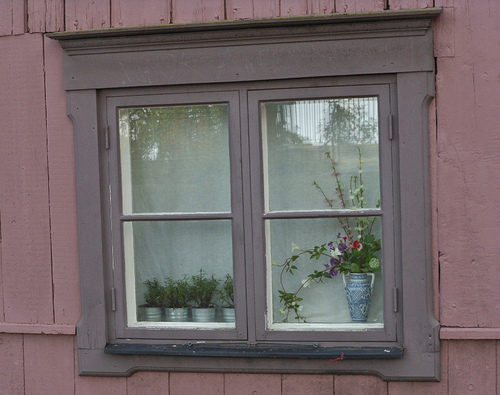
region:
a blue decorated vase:
[329, 240, 377, 325]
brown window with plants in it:
[51, 45, 436, 342]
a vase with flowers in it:
[288, 154, 410, 330]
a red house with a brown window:
[16, 42, 495, 369]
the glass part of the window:
[106, 100, 388, 329]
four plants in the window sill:
[137, 260, 274, 337]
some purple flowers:
[314, 236, 347, 288]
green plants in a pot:
[121, 254, 249, 333]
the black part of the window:
[103, 333, 410, 365]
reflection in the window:
[246, 78, 402, 165]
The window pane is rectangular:
[119, 108, 236, 328]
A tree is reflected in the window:
[138, 113, 224, 150]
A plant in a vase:
[288, 165, 383, 324]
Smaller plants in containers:
[145, 284, 235, 320]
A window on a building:
[112, 105, 378, 322]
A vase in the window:
[341, 272, 377, 319]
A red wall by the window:
[451, 128, 491, 370]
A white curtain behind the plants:
[148, 128, 220, 265]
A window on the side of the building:
[113, 99, 385, 320]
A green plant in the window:
[300, 159, 384, 271]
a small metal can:
[138, 304, 160, 322]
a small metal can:
[161, 302, 187, 320]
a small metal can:
[191, 303, 215, 324]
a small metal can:
[217, 306, 234, 323]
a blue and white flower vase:
[334, 264, 378, 323]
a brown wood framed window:
[98, 75, 406, 348]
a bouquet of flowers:
[278, 145, 383, 323]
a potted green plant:
[134, 276, 163, 324]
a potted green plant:
[161, 273, 188, 322]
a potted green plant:
[187, 273, 216, 323]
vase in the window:
[353, 268, 384, 324]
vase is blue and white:
[346, 270, 378, 317]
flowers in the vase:
[335, 212, 391, 285]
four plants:
[144, 284, 239, 326]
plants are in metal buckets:
[143, 298, 251, 319]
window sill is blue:
[191, 346, 237, 357]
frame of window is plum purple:
[98, 91, 199, 353]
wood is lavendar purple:
[2, 128, 45, 254]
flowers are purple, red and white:
[321, 223, 361, 269]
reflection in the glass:
[299, 124, 335, 169]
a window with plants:
[16, 12, 461, 392]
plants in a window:
[18, 15, 447, 392]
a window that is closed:
[29, 5, 497, 383]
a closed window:
[15, 5, 442, 394]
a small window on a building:
[64, 47, 484, 393]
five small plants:
[97, 240, 294, 347]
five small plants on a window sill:
[97, 232, 316, 358]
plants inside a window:
[47, 20, 465, 394]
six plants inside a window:
[33, 26, 485, 393]